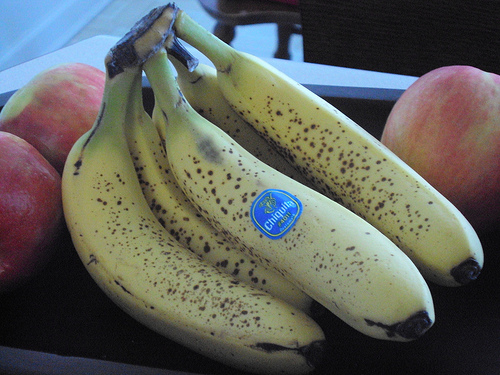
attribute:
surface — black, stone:
[1, 70, 498, 374]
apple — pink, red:
[373, 66, 499, 243]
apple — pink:
[0, 50, 129, 163]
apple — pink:
[0, 119, 67, 291]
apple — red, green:
[386, 32, 488, 179]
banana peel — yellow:
[287, 222, 375, 285]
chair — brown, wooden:
[200, 0, 302, 60]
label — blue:
[241, 189, 312, 243]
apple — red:
[0, 130, 63, 287]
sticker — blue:
[253, 187, 301, 234]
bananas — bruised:
[63, 19, 433, 350]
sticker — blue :
[169, 157, 372, 277]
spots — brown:
[139, 228, 196, 300]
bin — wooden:
[4, 31, 478, 368]